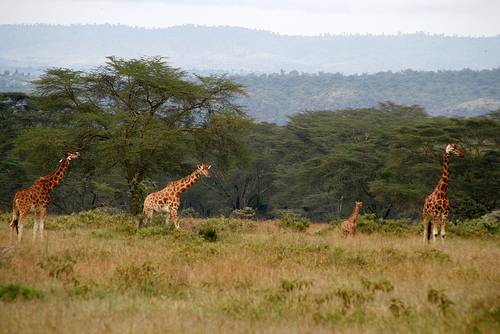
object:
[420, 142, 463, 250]
animals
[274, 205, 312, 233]
bushes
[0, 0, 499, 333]
background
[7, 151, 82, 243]
giraffe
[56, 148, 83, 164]
head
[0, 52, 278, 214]
trees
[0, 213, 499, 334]
field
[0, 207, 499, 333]
grass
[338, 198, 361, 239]
giraffe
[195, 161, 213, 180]
head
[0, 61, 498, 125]
mountains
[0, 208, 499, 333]
land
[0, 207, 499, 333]
grasslands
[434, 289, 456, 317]
plants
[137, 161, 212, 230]
giraffe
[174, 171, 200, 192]
neck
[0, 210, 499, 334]
ground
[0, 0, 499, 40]
sky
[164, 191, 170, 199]
spots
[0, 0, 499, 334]
scene